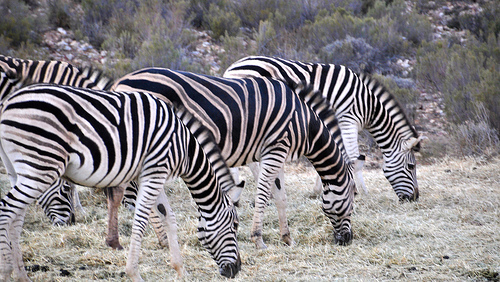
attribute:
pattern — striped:
[204, 73, 294, 153]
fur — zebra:
[219, 90, 269, 140]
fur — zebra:
[63, 99, 154, 169]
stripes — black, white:
[64, 84, 157, 154]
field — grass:
[18, 146, 480, 280]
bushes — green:
[29, 19, 485, 113]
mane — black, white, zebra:
[298, 80, 347, 180]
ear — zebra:
[403, 131, 426, 151]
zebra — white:
[7, 85, 252, 266]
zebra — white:
[111, 66, 361, 244]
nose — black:
[213, 259, 251, 276]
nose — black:
[330, 217, 356, 248]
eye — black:
[226, 217, 243, 234]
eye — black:
[352, 184, 361, 204]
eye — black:
[403, 161, 417, 170]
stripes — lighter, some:
[150, 79, 309, 138]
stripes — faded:
[119, 172, 179, 272]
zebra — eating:
[1, 76, 246, 280]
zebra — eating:
[169, 64, 359, 255]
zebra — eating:
[312, 55, 427, 208]